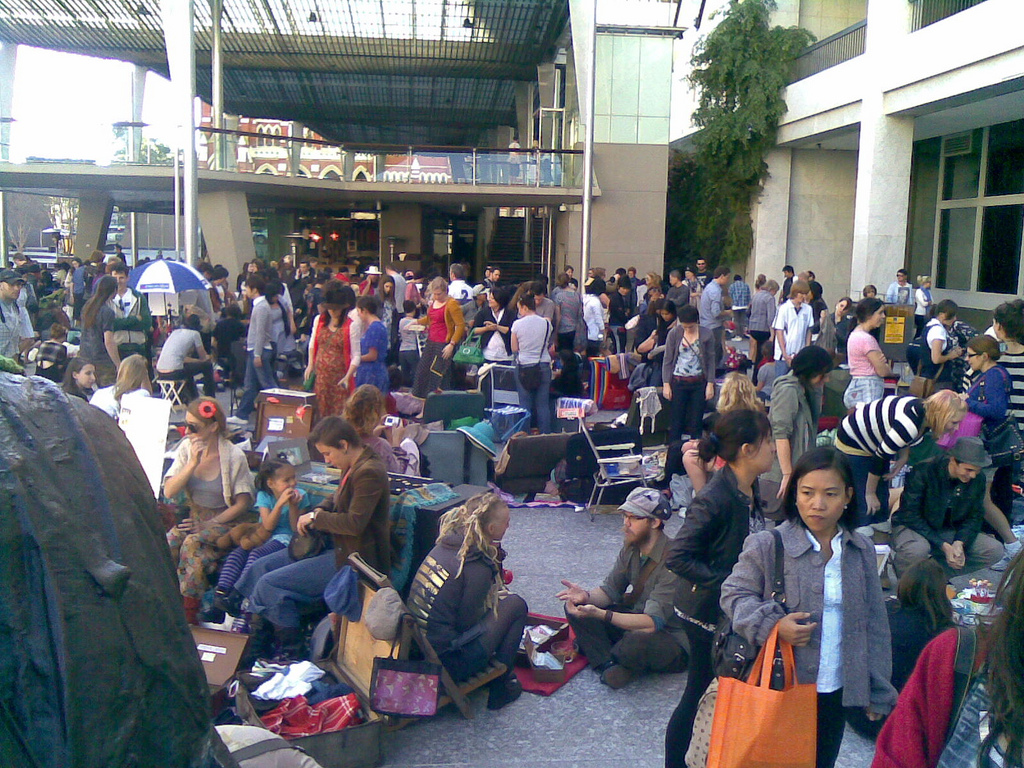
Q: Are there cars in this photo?
A: No, there are no cars.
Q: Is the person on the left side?
A: Yes, the person is on the left of the image.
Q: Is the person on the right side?
A: No, the person is on the left of the image.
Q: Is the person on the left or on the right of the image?
A: The person is on the left of the image.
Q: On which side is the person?
A: The person is on the left of the image.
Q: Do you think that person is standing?
A: Yes, the person is standing.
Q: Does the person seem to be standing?
A: Yes, the person is standing.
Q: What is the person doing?
A: The person is standing.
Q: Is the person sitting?
A: No, the person is standing.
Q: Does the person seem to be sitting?
A: No, the person is standing.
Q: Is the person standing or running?
A: The person is standing.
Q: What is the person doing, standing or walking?
A: The person is standing.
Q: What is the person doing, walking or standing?
A: The person is standing.